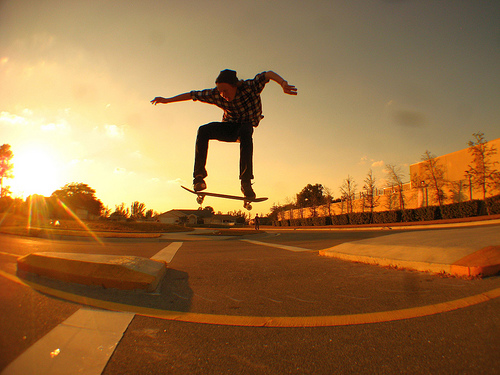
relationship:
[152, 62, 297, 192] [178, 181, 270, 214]
boy on skateboard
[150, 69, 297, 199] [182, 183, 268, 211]
boy riding on skateboard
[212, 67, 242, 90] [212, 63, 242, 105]
hat on head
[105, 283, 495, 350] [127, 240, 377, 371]
stripe running down road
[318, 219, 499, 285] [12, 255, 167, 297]
panel with horizontal angles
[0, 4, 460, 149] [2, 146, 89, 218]
sky with light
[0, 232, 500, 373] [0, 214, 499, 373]
pavement in skate park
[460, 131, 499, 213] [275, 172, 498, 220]
shrub along wall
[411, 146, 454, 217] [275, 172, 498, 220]
shrub along wall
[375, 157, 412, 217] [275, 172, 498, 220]
shrub along wall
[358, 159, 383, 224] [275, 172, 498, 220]
shrub along wall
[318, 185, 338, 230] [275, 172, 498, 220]
shrub along wall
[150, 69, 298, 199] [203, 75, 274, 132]
teenager wearing plaid shirt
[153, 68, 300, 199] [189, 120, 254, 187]
teenager wearing blue jeans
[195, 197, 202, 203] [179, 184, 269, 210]
wheel underneath skateboard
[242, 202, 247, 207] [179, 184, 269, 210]
wheel underneath skateboard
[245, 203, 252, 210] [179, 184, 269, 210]
wheel underneath skateboard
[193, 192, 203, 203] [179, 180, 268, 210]
wheels on skateboard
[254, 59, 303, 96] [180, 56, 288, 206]
arm on skateboarder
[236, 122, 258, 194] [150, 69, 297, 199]
left leg of boy